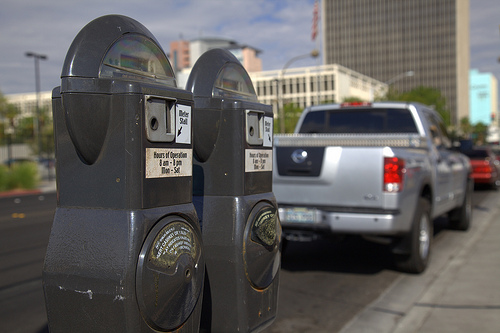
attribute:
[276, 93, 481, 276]
truck — gray, silver, parked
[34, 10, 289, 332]
parking meter — gray, side by side, black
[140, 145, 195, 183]
sticker — white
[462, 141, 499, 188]
car — red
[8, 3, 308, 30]
sky — blue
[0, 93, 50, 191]
trees — green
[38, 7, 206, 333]
meter — grey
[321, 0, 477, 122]
building — tall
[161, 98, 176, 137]
slot — coin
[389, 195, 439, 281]
tire — black, back tire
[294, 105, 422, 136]
window — rear window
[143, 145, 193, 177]
sign — hours of operation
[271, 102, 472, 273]
truck — silver